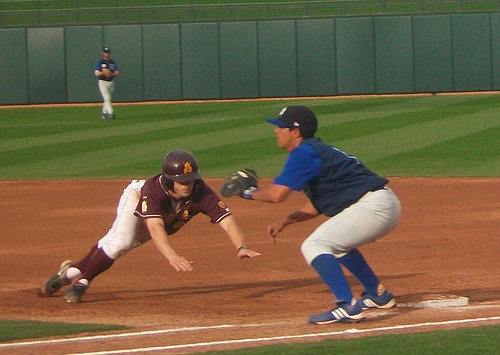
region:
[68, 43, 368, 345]
Men who are playing baseball.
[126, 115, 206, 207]
Helmet on the man.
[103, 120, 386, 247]
Man holding a mitt.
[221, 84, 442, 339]
Man in blue.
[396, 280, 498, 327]
Plate on the baseball field.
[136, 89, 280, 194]
Grass on the field.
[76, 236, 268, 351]
White lines on the field.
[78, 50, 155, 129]
Man in the background.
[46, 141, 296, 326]
Man diving in a game of baseball.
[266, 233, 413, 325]
Blue socks on the man.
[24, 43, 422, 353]
three baseball players on a field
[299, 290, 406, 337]
blue baseball cleats on player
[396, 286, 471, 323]
white base plate on a field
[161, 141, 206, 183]
helmet on a baseball player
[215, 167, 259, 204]
glove of a baseball player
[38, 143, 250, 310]
baseball player sliding into base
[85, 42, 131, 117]
baseball player in the outfield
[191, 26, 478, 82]
green fence behind field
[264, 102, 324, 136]
baseball cap on a player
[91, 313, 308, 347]
white chalk lines on a field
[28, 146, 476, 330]
baseball player reaching for base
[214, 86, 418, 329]
baseball player waiting for ball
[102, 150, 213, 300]
burgundy and white uniform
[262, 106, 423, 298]
blue and white uniform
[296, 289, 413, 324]
blue and white cleats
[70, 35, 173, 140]
baseball player in outfield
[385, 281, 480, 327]
white bag on baseball field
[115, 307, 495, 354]
chalk lines on dirt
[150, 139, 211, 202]
burgundy helmet with orange letter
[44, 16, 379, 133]
green fence behind outfielder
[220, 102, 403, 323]
player waiting to catch ball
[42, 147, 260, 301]
player diving for the base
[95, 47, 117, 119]
a player standing in the outfield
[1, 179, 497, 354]
dirt-covered part of the baseball field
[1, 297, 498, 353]
white lines on the baseball field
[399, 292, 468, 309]
a white base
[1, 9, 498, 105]
a green, padded wall behind the players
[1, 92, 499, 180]
grassy part of the baseball field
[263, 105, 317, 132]
a blue hat on the baseman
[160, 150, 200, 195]
a red helmet on the player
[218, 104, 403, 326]
A catcher with a glove.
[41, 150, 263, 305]
A man in a uniform.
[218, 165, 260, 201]
A black baseball glove.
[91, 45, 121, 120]
A man in the outfield.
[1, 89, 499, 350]
A green baseball field.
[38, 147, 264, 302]
A man diving for the plate.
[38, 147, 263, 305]
A man in a maroon uniform.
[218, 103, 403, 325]
A man in a blue uniform.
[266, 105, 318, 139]
A blue and black hat.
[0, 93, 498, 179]
Green grass on a field.